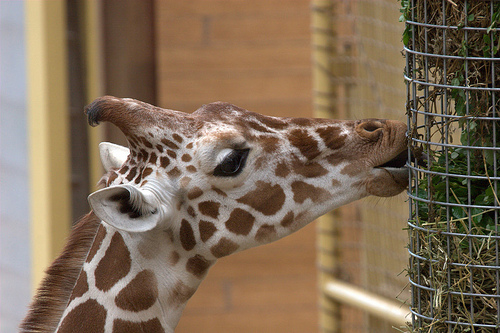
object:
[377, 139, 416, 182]
mouth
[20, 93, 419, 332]
giraffe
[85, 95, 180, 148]
horn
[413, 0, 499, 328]
hay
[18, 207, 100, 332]
mane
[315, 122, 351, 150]
spot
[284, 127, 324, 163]
spot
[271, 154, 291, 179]
spot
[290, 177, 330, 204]
spot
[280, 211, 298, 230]
spot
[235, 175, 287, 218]
spot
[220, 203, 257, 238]
spot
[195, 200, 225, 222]
spot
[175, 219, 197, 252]
spot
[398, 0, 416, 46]
plant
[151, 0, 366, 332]
wall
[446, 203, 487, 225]
leaves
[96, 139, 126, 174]
ear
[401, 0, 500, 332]
container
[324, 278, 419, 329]
pole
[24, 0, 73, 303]
paint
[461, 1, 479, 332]
wire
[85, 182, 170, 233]
ear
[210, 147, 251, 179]
eye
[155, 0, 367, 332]
door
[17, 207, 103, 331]
hair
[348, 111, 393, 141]
nose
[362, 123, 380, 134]
hole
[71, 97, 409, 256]
head